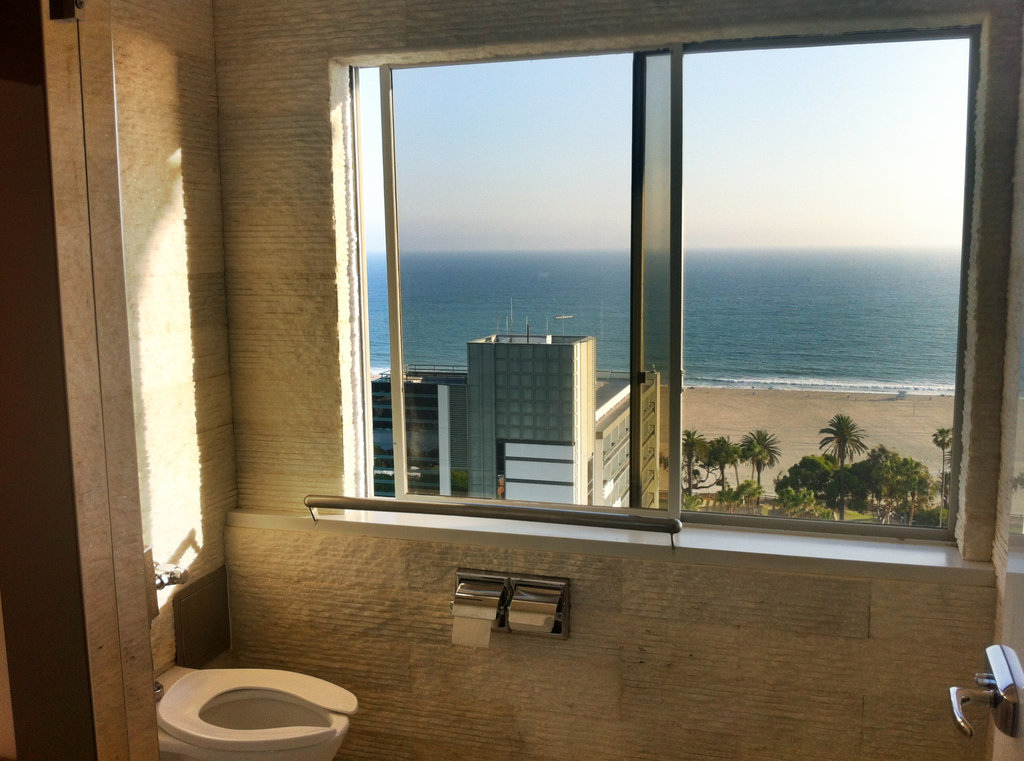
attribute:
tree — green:
[817, 411, 865, 520]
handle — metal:
[943, 677, 993, 732]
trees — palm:
[734, 396, 916, 509]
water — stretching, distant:
[419, 245, 945, 386]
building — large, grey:
[421, 331, 659, 543]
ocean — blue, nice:
[605, 234, 910, 425]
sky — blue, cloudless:
[605, 91, 901, 280]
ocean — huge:
[492, 245, 951, 401]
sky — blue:
[384, 39, 977, 247]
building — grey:
[361, 323, 660, 516]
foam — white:
[741, 374, 949, 411]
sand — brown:
[708, 392, 907, 423]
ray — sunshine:
[136, 206, 292, 516]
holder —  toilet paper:
[442, 551, 574, 653]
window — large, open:
[360, 78, 957, 554]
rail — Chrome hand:
[283, 482, 692, 571]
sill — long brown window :
[352, 57, 940, 548]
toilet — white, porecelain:
[162, 662, 366, 753]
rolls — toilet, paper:
[447, 589, 553, 646]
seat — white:
[158, 657, 385, 757]